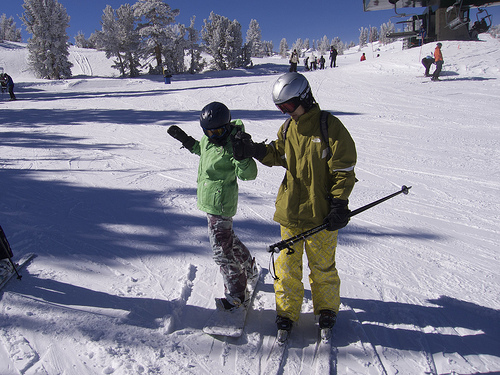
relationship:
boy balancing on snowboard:
[165, 101, 257, 311] [214, 256, 256, 349]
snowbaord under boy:
[202, 262, 261, 338] [165, 101, 257, 311]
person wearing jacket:
[432, 40, 447, 77] [433, 46, 447, 63]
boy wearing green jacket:
[165, 101, 257, 311] [188, 136, 258, 217]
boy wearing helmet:
[165, 101, 257, 311] [198, 99, 231, 131]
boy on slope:
[165, 101, 257, 311] [0, 31, 500, 373]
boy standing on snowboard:
[163, 102, 293, 329] [202, 261, 264, 339]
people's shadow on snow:
[7, 264, 498, 361] [3, 35, 498, 372]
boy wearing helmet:
[165, 101, 257, 311] [197, 101, 229, 144]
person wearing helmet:
[233, 71, 356, 347] [272, 68, 315, 115]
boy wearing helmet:
[165, 101, 257, 311] [195, 98, 236, 140]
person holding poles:
[233, 71, 356, 347] [268, 184, 421, 271]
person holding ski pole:
[233, 71, 356, 347] [266, 185, 413, 256]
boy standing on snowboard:
[165, 101, 257, 311] [199, 257, 260, 339]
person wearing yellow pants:
[233, 71, 356, 347] [267, 247, 354, 320]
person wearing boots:
[233, 71, 356, 347] [277, 305, 344, 330]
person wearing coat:
[233, 71, 356, 347] [247, 113, 357, 228]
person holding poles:
[228, 71, 377, 346] [259, 160, 417, 281]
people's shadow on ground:
[2, 265, 500, 358] [2, 36, 498, 373]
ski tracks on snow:
[433, 170, 483, 241] [3, 35, 498, 372]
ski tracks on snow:
[461, 75, 486, 101] [3, 35, 498, 372]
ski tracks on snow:
[353, 317, 434, 370] [3, 35, 498, 372]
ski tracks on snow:
[97, 231, 138, 291] [3, 35, 498, 372]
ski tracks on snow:
[151, 146, 179, 186] [3, 35, 498, 372]